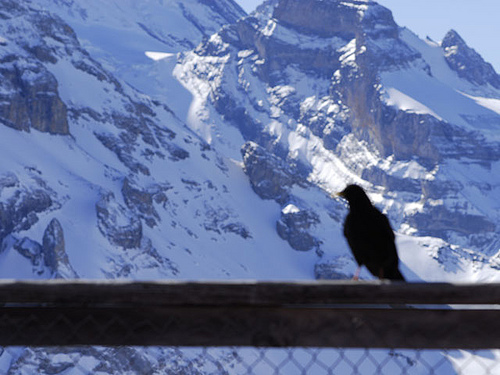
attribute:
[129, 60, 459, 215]
mountain — sunlit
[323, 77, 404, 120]
rock — brown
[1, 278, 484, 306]
wood — long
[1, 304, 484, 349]
wood — long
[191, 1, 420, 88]
peak — wide, circular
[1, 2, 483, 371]
mountain — snowy, sunlit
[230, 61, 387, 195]
layer — exposed, rock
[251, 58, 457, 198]
layer — exposed, rock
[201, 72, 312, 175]
layer — exposed, rock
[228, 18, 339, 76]
layer — exposed, rock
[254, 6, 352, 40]
layer — exposed, rock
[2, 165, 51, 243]
outcrop — large, jagged, smooth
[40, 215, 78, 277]
outcrop — large, jagged, smooth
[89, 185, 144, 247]
outcrop — large, jagged, smooth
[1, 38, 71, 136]
outcrop — large, jagged, smooth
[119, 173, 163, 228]
outcrop — large, jagged, smooth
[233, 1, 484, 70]
sky — pale blue, blue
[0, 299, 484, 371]
fencing — open, twisted wire, wire, metal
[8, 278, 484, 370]
fence — wooden, metal, meshed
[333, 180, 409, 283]
bird — black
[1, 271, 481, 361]
ledge — brown, wooden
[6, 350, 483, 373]
fence — chain link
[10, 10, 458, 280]
mountain — snow covered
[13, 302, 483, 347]
support beam — wooden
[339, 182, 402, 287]
bird — black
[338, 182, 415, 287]
bird — black